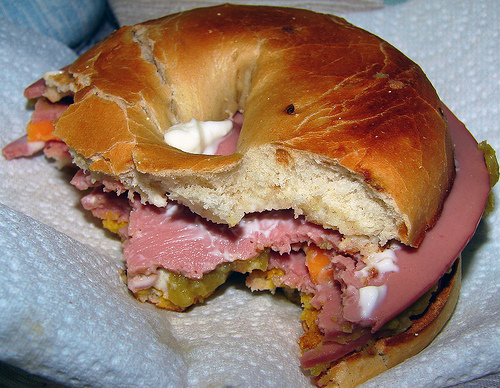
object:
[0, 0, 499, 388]
bagel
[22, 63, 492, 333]
bologna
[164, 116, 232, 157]
mayonaise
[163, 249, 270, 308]
pickle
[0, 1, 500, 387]
paper towel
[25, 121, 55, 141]
cheese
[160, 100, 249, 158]
hole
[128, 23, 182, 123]
crease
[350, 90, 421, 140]
dark spot